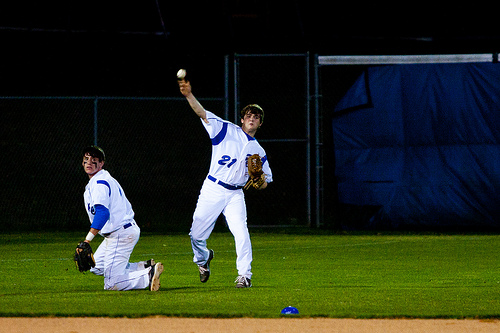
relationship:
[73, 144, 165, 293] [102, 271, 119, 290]
boy on h knee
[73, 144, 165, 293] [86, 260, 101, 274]
boy on h knee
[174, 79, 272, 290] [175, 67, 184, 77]
boy catching baseball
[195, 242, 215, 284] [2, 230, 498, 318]
foot off ground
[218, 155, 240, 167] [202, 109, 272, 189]
numbers on shirt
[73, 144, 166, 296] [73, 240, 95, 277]
boy wearing glove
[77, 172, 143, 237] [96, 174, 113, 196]
baseball shirt with blue trim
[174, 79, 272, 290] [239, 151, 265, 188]
boy baseball brown mitt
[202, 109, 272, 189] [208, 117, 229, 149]
shirt with trim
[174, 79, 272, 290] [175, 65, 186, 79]
boy throwing baseball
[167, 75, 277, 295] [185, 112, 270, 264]
boy wearing uniform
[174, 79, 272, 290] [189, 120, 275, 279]
boy in uniform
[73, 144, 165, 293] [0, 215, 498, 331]
boy kneeling on ground